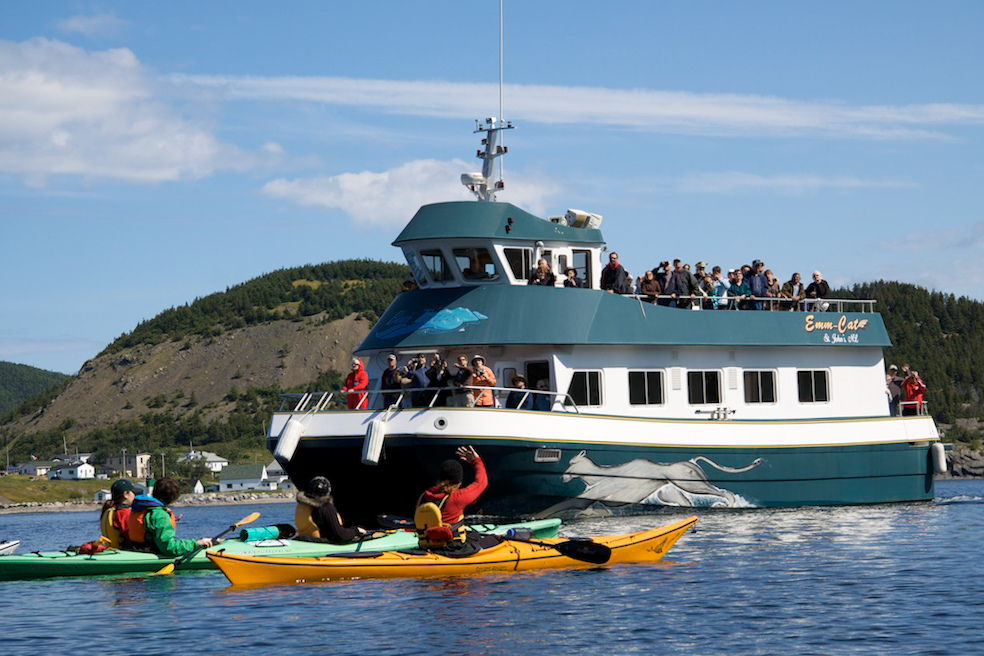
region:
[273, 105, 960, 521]
green and white boat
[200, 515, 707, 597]
kayak is color yellow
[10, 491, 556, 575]
kayak is color green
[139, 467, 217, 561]
man has green jacket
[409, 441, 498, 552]
woman is wearing red jacket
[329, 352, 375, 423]
woman is wearing red coat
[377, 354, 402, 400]
man is wearing black jacket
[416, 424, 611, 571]
woman is holding an oar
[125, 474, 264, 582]
man is holding an oar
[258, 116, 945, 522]
A big blue and white boat full of people.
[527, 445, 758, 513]
The animal painted on side of the large boat.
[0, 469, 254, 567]
A green kayak with two people in it.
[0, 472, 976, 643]
The body of water the boats are in.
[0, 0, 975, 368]
The clouds and sky over the water.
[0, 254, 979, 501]
The hilly landscape behind the boats.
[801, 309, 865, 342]
Words on the side of the boat's top deck.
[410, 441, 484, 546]
The person in the orange kayak waving.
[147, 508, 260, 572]
Paddle held by person in green kayak.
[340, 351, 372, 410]
woman wearing red coat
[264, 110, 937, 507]
white and slate blue colored boat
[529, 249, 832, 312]
people standing on top level of boat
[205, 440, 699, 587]
man in a yellow kayak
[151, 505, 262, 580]
black and yellow oar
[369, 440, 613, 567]
man waving and holding black oar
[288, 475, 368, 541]
person wearing yellow lifejacket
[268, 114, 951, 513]
large boat floating on the water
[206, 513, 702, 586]
long yellow and black kayak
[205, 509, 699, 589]
Man sitting in a yellow boat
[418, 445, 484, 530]
Man is wearing a red jacket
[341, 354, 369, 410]
Man is wearing a red jacket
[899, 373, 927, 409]
Man is wearing a red jacket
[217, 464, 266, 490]
White house in the background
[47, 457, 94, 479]
White house in the background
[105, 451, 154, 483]
White house in the background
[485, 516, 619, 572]
oar in man's hands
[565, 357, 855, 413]
windows on side of boat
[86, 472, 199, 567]
two men paddling a kayak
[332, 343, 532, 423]
passengers on a boat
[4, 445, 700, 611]
four people kayaking in the water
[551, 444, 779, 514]
design on side of boat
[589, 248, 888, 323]
passengers on top deck of boat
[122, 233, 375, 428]
hills behind the boat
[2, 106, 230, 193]
white clouds in the sky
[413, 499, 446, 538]
yellow life preserver on kayaker